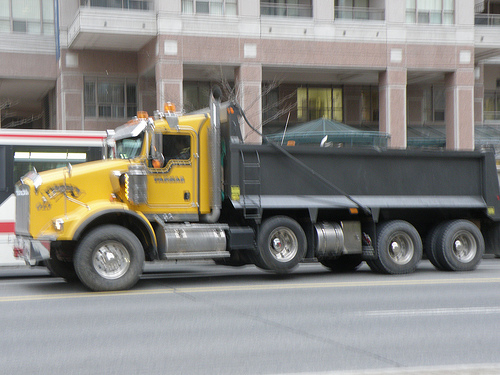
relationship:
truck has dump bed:
[12, 84, 500, 291] [221, 101, 499, 223]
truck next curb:
[12, 84, 500, 291] [2, 255, 498, 282]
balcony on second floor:
[64, 6, 156, 53] [5, 3, 498, 45]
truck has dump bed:
[12, 84, 500, 291] [215, 134, 495, 218]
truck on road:
[12, 84, 500, 291] [0, 259, 497, 373]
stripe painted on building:
[4, 124, 108, 146] [1, 0, 499, 202]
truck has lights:
[12, 84, 500, 291] [129, 86, 219, 123]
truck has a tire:
[32, 82, 480, 340] [378, 188, 432, 280]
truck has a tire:
[12, 84, 500, 291] [372, 216, 424, 275]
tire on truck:
[252, 212, 312, 276] [12, 84, 500, 291]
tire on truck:
[55, 223, 153, 291] [12, 84, 500, 291]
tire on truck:
[355, 215, 433, 285] [12, 84, 500, 291]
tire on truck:
[429, 212, 491, 272] [12, 84, 500, 291]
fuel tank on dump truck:
[163, 214, 239, 263] [22, 101, 479, 270]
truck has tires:
[12, 84, 500, 291] [253, 216, 486, 277]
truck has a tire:
[12, 84, 500, 291] [429, 212, 491, 272]